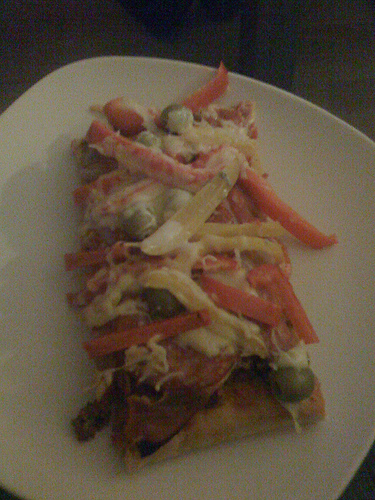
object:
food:
[64, 62, 338, 472]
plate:
[0, 55, 375, 498]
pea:
[271, 367, 314, 401]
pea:
[138, 286, 185, 320]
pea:
[124, 208, 157, 240]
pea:
[167, 107, 194, 134]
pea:
[138, 132, 153, 146]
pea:
[144, 289, 182, 318]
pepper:
[85, 119, 235, 194]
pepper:
[238, 167, 337, 248]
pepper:
[182, 60, 229, 113]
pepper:
[247, 263, 320, 344]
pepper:
[201, 274, 282, 326]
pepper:
[89, 312, 200, 356]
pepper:
[141, 158, 240, 256]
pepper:
[140, 267, 263, 349]